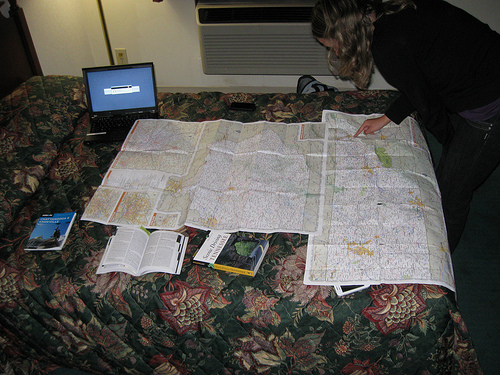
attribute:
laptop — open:
[78, 53, 168, 133]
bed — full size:
[0, 270, 431, 365]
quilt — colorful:
[163, 289, 283, 320]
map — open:
[120, 122, 321, 235]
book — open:
[96, 230, 185, 282]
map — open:
[326, 110, 451, 287]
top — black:
[385, 16, 485, 84]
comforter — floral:
[8, 114, 82, 173]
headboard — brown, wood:
[3, 28, 28, 86]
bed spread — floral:
[24, 139, 85, 172]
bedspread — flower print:
[3, 270, 69, 300]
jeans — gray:
[437, 157, 488, 199]